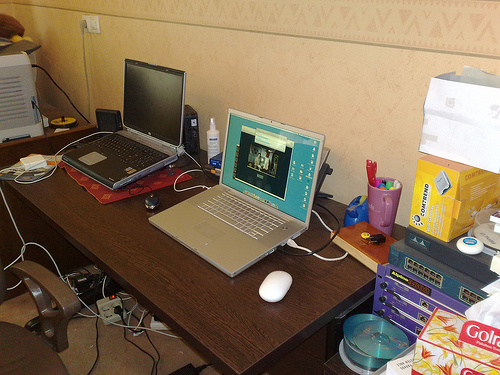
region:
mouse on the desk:
[248, 258, 295, 305]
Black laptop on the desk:
[67, 1, 178, 213]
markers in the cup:
[366, 151, 400, 196]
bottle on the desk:
[201, 109, 227, 171]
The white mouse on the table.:
[259, 268, 298, 303]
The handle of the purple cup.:
[379, 192, 394, 228]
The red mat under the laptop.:
[57, 148, 196, 196]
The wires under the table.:
[64, 263, 174, 374]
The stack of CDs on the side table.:
[343, 311, 409, 374]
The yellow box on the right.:
[404, 145, 499, 240]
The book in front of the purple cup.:
[332, 225, 396, 272]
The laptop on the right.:
[150, 109, 318, 276]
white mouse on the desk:
[251, 267, 296, 300]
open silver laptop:
[149, 106, 323, 284]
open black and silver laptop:
[60, 47, 187, 197]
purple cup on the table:
[365, 175, 396, 233]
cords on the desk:
[7, 122, 347, 282]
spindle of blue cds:
[335, 310, 416, 372]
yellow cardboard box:
[399, 154, 491, 238]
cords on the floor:
[7, 243, 179, 373]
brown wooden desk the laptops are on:
[1, 122, 384, 374]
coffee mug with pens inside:
[361, 162, 408, 225]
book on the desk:
[332, 216, 402, 266]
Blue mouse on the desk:
[136, 187, 168, 209]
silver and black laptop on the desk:
[85, 50, 185, 195]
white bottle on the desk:
[200, 115, 227, 165]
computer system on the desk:
[76, 48, 181, 198]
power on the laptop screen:
[221, 101, 320, 228]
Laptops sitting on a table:
[59, 58, 325, 278]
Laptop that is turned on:
[147, 108, 325, 277]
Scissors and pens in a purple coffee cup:
[365, 159, 403, 237]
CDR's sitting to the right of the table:
[336, 311, 406, 372]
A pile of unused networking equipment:
[370, 223, 497, 341]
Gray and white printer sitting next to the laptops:
[0, 37, 45, 139]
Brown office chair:
[0, 257, 71, 372]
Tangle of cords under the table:
[61, 260, 211, 372]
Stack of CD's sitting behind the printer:
[50, 115, 76, 127]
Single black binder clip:
[360, 231, 386, 246]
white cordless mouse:
[251, 270, 307, 308]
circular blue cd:
[348, 311, 423, 368]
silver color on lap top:
[139, 203, 249, 283]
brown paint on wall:
[237, 39, 381, 90]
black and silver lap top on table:
[54, 40, 194, 205]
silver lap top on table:
[149, 85, 333, 302]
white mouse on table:
[250, 255, 310, 315]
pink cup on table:
[349, 158, 412, 258]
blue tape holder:
[329, 185, 381, 246]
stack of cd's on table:
[330, 286, 406, 373]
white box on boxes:
[403, 66, 498, 178]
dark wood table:
[11, 149, 458, 373]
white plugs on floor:
[88, 271, 136, 343]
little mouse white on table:
[255, 268, 295, 304]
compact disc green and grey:
[356, 314, 406, 362]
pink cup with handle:
[370, 183, 395, 231]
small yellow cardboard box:
[414, 160, 467, 239]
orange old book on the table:
[336, 210, 395, 267]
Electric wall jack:
[80, 18, 101, 33]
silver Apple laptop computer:
[148, 108, 326, 278]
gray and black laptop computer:
[61, 58, 188, 190]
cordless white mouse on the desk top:
[259, 267, 292, 304]